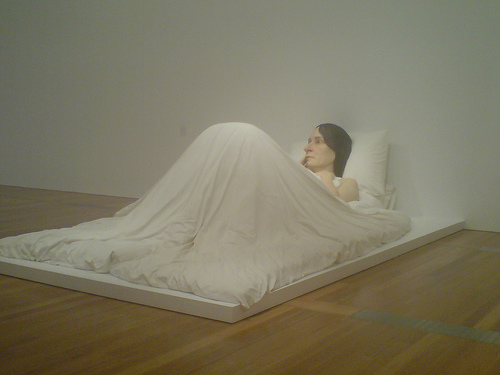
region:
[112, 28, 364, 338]
a bed on the floor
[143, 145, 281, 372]
a bed on the floor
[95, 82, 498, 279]
Woman lying on the floor.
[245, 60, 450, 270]
Woman resting on a pillow.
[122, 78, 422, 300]
Blanket on the woman.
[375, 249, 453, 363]
Wood floor under the woman.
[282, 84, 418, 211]
Woman with brunette hair.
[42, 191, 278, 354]
Platform on the floor.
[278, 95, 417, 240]
Woman with a large nose.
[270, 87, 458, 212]
Pillow against the wall.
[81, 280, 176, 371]
Lines on the floor.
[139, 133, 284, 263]
Wrinkles on the blanket.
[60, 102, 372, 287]
a woman laying in bed.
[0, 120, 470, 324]
a bed laying on a hardwood floor.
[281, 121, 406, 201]
a pillow pressed up against a wall.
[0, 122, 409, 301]
a blanket on top of a bed.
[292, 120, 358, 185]
the head of a woman.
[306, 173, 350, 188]
a section of a white top.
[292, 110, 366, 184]
a woman with dark hair.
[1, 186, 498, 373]
a floor made out of wood.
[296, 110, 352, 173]
a woman with a pale face.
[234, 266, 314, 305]
a section of wrinkled bedding.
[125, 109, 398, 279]
sculpture of woman in bed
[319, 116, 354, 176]
brown hair of woman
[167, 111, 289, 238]
lump under white sheet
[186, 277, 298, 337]
edge of white square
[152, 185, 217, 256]
wrinkles in bed sheet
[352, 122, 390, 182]
pillow propped against wall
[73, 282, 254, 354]
wood floor under sculpture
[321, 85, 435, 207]
white wall behind sculture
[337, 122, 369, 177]
head on white pillow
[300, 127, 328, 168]
face of sculpured woman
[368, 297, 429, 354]
part of a floor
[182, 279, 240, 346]
edge of a door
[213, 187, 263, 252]
part of a sheet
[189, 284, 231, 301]
edge of a sheet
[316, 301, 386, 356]
part of a floor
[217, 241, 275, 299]
part of a matress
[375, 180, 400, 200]
part of a pillow